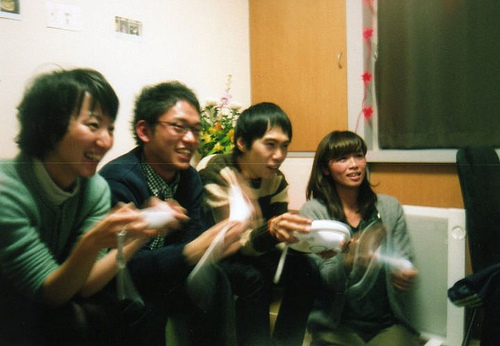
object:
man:
[195, 102, 350, 346]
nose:
[271, 144, 285, 162]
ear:
[236, 136, 246, 153]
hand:
[272, 209, 312, 242]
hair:
[306, 130, 380, 223]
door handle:
[336, 52, 343, 69]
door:
[248, 0, 347, 151]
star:
[361, 105, 373, 120]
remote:
[109, 201, 175, 310]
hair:
[230, 102, 291, 161]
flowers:
[228, 104, 243, 116]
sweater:
[297, 192, 420, 337]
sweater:
[195, 150, 289, 257]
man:
[98, 80, 258, 345]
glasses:
[135, 120, 202, 134]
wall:
[0, 0, 251, 172]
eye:
[336, 157, 349, 162]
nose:
[348, 155, 359, 170]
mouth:
[346, 172, 362, 181]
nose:
[180, 126, 196, 144]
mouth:
[265, 165, 280, 173]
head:
[320, 130, 367, 188]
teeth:
[352, 173, 355, 176]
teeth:
[274, 166, 278, 168]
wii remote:
[184, 183, 252, 313]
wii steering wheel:
[273, 219, 356, 284]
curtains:
[374, 0, 499, 150]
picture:
[114, 16, 142, 36]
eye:
[352, 154, 364, 158]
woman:
[295, 130, 422, 345]